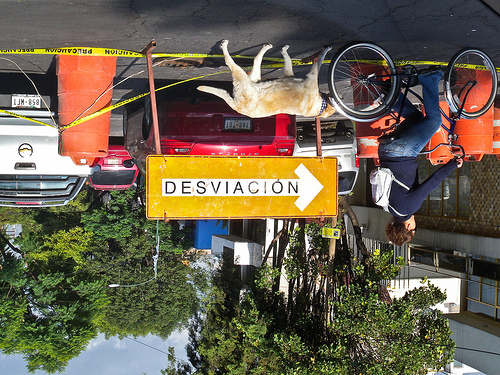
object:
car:
[88, 144, 139, 192]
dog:
[197, 37, 334, 122]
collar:
[316, 94, 327, 117]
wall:
[467, 148, 496, 223]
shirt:
[378, 155, 460, 220]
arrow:
[160, 164, 325, 212]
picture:
[2, 6, 498, 373]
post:
[107, 208, 179, 289]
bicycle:
[329, 42, 498, 165]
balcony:
[207, 232, 260, 267]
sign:
[147, 154, 335, 217]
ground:
[40, 14, 469, 55]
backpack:
[366, 165, 399, 206]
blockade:
[54, 50, 116, 166]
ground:
[458, 107, 485, 156]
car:
[0, 93, 93, 208]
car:
[294, 122, 361, 196]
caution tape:
[0, 46, 498, 75]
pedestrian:
[336, 42, 473, 246]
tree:
[222, 223, 469, 372]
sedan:
[121, 83, 297, 155]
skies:
[93, 346, 146, 368]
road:
[1, 2, 497, 121]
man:
[367, 57, 464, 244]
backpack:
[368, 165, 412, 220]